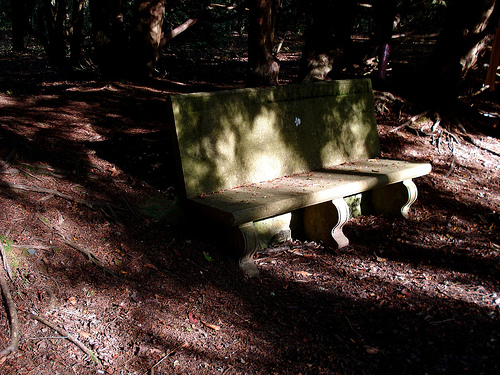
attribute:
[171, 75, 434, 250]
bench — cement,  trees', stone,  stone, granite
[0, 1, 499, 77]
trees —  brown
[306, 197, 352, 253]
legs —  stone,   bench's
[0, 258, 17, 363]
roots — brown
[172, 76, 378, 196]
moss —  green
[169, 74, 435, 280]
chair —  stone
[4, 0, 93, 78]
background —  dark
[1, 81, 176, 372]
rotting leaves — brown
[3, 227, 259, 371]
ground —  reddish brown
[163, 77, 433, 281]
bench —  stone,  dirty